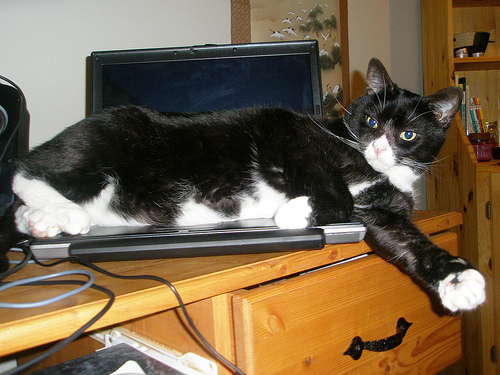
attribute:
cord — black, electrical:
[3, 237, 249, 370]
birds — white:
[264, 7, 341, 66]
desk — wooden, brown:
[0, 206, 468, 370]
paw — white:
[438, 266, 493, 319]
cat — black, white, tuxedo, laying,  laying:
[12, 50, 493, 306]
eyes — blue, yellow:
[365, 109, 425, 148]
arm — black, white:
[358, 190, 498, 319]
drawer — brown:
[234, 223, 478, 372]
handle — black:
[348, 314, 418, 367]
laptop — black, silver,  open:
[31, 30, 363, 266]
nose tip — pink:
[369, 142, 389, 160]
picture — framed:
[234, 0, 359, 120]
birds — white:
[263, 7, 339, 58]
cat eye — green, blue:
[360, 112, 384, 135]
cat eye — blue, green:
[392, 125, 428, 149]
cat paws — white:
[10, 168, 87, 244]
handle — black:
[341, 312, 418, 366]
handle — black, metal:
[341, 309, 417, 363]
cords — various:
[2, 239, 255, 372]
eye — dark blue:
[363, 113, 382, 131]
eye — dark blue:
[393, 125, 419, 145]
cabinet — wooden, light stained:
[417, 1, 483, 372]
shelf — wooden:
[417, 1, 483, 371]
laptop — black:
[22, 37, 372, 281]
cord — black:
[23, 248, 249, 373]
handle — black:
[333, 313, 414, 361]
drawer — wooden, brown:
[218, 231, 467, 371]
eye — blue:
[361, 113, 384, 132]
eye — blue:
[393, 127, 418, 147]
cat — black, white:
[0, 51, 485, 326]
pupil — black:
[361, 114, 381, 130]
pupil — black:
[394, 127, 420, 146]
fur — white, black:
[27, 109, 428, 248]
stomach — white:
[83, 169, 351, 259]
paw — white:
[420, 250, 498, 315]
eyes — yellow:
[347, 109, 431, 167]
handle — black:
[341, 298, 445, 371]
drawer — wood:
[288, 247, 465, 372]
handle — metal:
[338, 319, 404, 369]